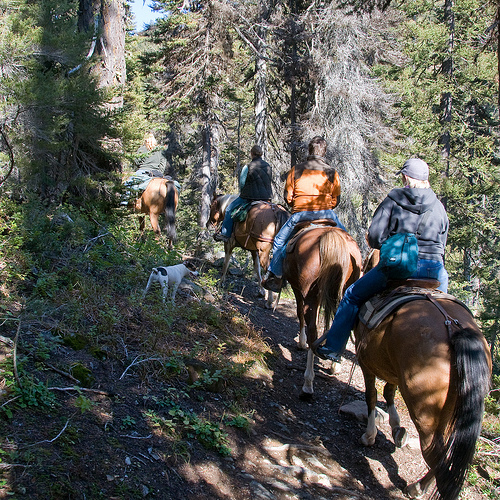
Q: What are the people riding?
A: Horses.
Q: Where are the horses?
A: In the forest.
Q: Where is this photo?
A: In the woods.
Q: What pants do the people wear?
A: Jeans.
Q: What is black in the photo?
A: The horse's' tail.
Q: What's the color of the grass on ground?
A: Green.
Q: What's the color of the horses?
A: Brown.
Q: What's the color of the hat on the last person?
A: Gray.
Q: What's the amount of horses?
A: Four.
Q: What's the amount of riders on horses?
A: Four.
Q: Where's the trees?
A: Side of trail.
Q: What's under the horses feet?
A: Dirt trail.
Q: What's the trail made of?
A: Dirt.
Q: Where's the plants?
A: Near dirt trail.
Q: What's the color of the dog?
A: Black and white.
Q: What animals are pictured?
A: Horses.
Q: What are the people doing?
A: Horseback riding.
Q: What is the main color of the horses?
A: Browns.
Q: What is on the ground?
A: Shadows.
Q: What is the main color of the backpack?
A: Blue.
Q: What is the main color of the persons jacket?
A: Orange.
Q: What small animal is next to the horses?
A: Dog.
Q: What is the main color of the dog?
A: Black and white.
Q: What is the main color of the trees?
A: Green.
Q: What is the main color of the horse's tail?
A: Black.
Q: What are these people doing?
A: Riding horses.